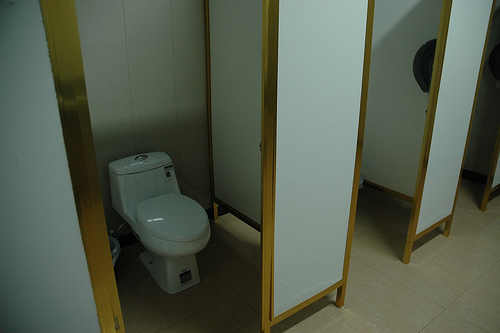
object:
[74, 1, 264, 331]
stall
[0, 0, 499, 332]
public bathroom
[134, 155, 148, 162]
flush button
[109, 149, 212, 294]
toilet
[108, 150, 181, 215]
toilet tank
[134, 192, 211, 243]
seat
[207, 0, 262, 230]
wall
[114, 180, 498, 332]
floor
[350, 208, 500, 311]
tile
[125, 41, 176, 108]
tile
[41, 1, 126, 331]
trim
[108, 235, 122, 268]
garbage can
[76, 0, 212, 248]
wall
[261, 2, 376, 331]
wall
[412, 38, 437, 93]
paper dispenser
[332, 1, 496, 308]
stall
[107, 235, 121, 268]
bag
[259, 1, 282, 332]
trim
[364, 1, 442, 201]
wall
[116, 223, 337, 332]
shadow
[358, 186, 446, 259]
shadow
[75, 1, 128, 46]
tile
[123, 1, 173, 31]
tile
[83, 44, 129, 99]
tile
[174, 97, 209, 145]
tile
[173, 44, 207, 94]
tile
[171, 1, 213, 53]
tile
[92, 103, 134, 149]
tile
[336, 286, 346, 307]
leg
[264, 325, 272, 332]
leg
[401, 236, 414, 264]
leg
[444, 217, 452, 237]
leg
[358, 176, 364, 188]
garbage can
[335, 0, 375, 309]
trim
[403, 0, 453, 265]
trim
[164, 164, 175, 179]
label